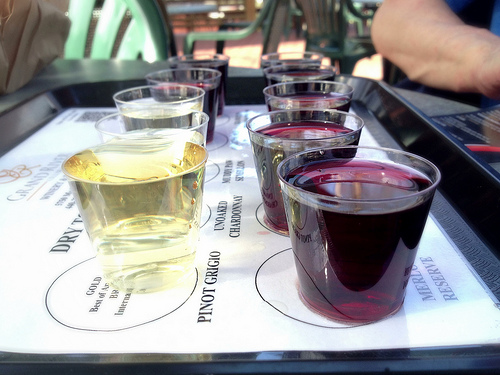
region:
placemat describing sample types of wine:
[5, 90, 495, 348]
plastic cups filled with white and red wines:
[60, 46, 438, 326]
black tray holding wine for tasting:
[6, 52, 494, 367]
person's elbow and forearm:
[366, 2, 494, 103]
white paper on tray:
[3, 80, 498, 366]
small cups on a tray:
[29, 18, 456, 351]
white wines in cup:
[59, 82, 229, 284]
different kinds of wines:
[63, 39, 459, 328]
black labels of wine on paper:
[2, 80, 474, 346]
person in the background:
[340, 5, 497, 125]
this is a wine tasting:
[3, 5, 499, 374]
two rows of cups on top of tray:
[0, 48, 499, 372]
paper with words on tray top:
[0, 72, 499, 374]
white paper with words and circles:
[0, 103, 494, 353]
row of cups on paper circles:
[245, 51, 441, 327]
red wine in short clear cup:
[275, 146, 441, 324]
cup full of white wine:
[66, 145, 207, 291]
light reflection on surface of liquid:
[280, 144, 439, 322]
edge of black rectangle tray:
[0, 72, 498, 373]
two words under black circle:
[43, 246, 220, 333]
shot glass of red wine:
[273, 143, 443, 325]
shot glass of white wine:
[61, 136, 211, 291]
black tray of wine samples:
[0, 68, 499, 373]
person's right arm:
[369, 0, 499, 97]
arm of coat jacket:
[1, 0, 73, 91]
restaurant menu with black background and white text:
[431, 103, 498, 163]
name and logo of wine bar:
[0, 151, 73, 208]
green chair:
[72, 0, 172, 62]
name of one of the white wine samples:
[195, 248, 223, 327]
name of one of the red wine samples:
[405, 250, 462, 305]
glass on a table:
[271, 156, 444, 321]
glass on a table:
[61, 133, 222, 299]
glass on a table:
[231, 108, 352, 151]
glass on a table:
[262, 83, 347, 114]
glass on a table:
[266, 65, 346, 85]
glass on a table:
[261, 40, 326, 70]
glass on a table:
[175, 40, 226, 63]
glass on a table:
[156, 60, 224, 85]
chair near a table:
[117, 5, 177, 55]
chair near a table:
[295, 3, 365, 56]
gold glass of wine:
[49, 102, 229, 304]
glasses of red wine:
[227, 50, 435, 309]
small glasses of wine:
[27, 126, 447, 354]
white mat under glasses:
[12, 84, 427, 341]